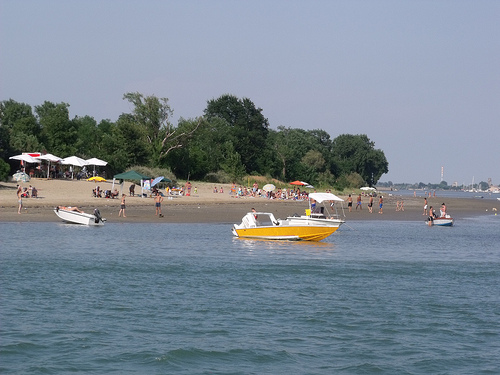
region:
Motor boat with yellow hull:
[230, 205, 336, 252]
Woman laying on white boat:
[45, 197, 85, 214]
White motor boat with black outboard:
[51, 207, 109, 227]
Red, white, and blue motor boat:
[422, 210, 467, 232]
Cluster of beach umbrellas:
[15, 150, 110, 174]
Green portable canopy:
[106, 165, 151, 198]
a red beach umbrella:
[281, 175, 311, 191]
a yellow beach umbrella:
[86, 172, 110, 187]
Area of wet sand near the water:
[2, 197, 483, 227]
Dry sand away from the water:
[5, 172, 321, 199]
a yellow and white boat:
[234, 210, 341, 239]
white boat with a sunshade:
[285, 191, 344, 226]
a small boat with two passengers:
[418, 200, 454, 230]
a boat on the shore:
[53, 202, 104, 226]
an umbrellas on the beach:
[9, 149, 40, 178]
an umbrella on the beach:
[39, 150, 60, 176]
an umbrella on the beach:
[60, 155, 87, 177]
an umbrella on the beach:
[85, 155, 107, 181]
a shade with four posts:
[109, 167, 154, 200]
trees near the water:
[329, 134, 390, 189]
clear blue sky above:
[124, 21, 495, 54]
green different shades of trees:
[39, 99, 358, 165]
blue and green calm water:
[152, 275, 346, 322]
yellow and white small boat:
[237, 210, 366, 257]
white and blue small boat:
[49, 203, 117, 231]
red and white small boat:
[432, 209, 479, 241]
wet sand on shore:
[176, 203, 233, 218]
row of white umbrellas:
[24, 142, 124, 164]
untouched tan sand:
[43, 186, 98, 204]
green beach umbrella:
[104, 166, 161, 185]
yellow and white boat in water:
[209, 191, 381, 248]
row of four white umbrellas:
[14, 143, 129, 174]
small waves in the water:
[123, 298, 292, 365]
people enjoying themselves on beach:
[34, 151, 423, 231]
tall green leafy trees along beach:
[32, 91, 362, 175]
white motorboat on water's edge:
[49, 196, 111, 232]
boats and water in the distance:
[389, 166, 499, 201]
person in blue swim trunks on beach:
[142, 181, 179, 227]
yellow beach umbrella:
[82, 170, 109, 202]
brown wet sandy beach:
[179, 198, 231, 227]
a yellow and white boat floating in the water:
[228, 199, 353, 252]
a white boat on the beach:
[34, 200, 105, 228]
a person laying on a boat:
[51, 200, 85, 225]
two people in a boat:
[420, 199, 456, 236]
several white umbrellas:
[9, 154, 110, 172]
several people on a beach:
[212, 172, 326, 213]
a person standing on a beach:
[147, 192, 165, 216]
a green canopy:
[111, 172, 151, 204]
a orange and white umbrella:
[291, 176, 311, 188]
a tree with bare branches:
[143, 111, 200, 163]